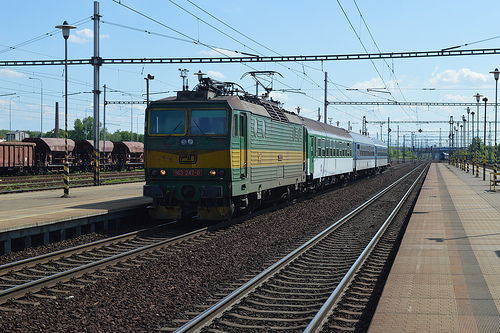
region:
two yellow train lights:
[130, 153, 239, 179]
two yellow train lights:
[141, 162, 223, 190]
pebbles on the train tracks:
[118, 253, 207, 308]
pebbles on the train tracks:
[264, 212, 311, 254]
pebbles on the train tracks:
[219, 247, 267, 274]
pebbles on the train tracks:
[205, 192, 318, 287]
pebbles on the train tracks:
[97, 273, 169, 331]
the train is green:
[139, 78, 369, 229]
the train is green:
[109, 68, 256, 238]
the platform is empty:
[369, 76, 497, 295]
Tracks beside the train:
[167, 162, 428, 332]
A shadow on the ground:
[75, 195, 218, 237]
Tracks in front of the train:
[0, 213, 218, 309]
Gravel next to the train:
[9, 160, 411, 331]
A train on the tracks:
[141, 80, 388, 215]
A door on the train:
[238, 112, 248, 176]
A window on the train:
[148, 108, 228, 134]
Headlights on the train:
[153, 165, 223, 176]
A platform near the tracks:
[367, 161, 497, 331]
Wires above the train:
[334, 2, 421, 124]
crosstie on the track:
[248, 299, 300, 319]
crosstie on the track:
[258, 293, 312, 305]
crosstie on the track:
[281, 281, 313, 291]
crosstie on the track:
[280, 273, 315, 285]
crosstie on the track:
[292, 265, 322, 275]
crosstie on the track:
[245, 313, 278, 326]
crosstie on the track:
[242, 320, 272, 331]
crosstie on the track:
[332, 243, 349, 254]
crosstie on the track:
[303, 260, 330, 268]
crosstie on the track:
[300, 268, 323, 278]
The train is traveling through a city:
[1, 12, 491, 310]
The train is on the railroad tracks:
[7, 43, 482, 314]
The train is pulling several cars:
[10, 20, 485, 323]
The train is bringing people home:
[12, 32, 484, 322]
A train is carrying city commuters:
[10, 35, 480, 310]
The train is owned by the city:
[25, 22, 481, 312]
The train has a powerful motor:
[15, 31, 480, 331]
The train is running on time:
[5, 42, 490, 309]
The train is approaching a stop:
[10, 32, 490, 322]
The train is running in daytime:
[32, 24, 490, 315]